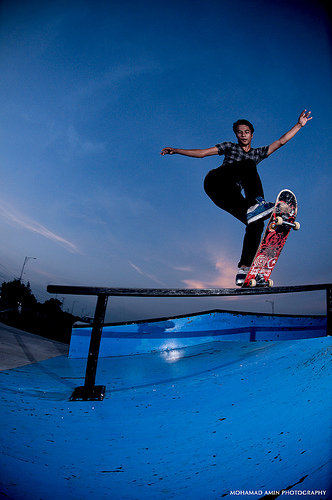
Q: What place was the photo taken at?
A: It was taken at the skate park.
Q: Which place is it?
A: It is a skate park.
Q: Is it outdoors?
A: Yes, it is outdoors.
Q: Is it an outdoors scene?
A: Yes, it is outdoors.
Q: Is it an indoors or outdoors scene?
A: It is outdoors.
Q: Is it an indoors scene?
A: No, it is outdoors.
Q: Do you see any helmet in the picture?
A: No, there are no helmets.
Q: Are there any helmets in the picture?
A: No, there are no helmets.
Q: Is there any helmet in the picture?
A: No, there are no helmets.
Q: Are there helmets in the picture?
A: No, there are no helmets.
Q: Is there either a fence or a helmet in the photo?
A: No, there are no helmets or fences.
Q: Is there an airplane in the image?
A: No, there are no airplanes.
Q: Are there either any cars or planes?
A: No, there are no planes or cars.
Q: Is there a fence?
A: No, there are no fences.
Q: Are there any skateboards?
A: Yes, there is a skateboard.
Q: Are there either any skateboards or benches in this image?
A: Yes, there is a skateboard.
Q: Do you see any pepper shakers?
A: No, there are no pepper shakers.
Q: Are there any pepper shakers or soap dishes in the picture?
A: No, there are no pepper shakers or soap dishes.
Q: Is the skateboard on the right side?
A: Yes, the skateboard is on the right of the image.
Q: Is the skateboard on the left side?
A: No, the skateboard is on the right of the image.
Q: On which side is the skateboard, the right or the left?
A: The skateboard is on the right of the image.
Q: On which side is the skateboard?
A: The skateboard is on the right of the image.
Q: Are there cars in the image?
A: No, there are no cars.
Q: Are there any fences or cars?
A: No, there are no cars or fences.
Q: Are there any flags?
A: No, there are no flags.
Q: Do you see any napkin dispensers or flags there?
A: No, there are no flags or napkin dispensers.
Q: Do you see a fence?
A: No, there are no fences.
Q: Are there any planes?
A: No, there are no planes.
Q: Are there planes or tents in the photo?
A: No, there are no planes or tents.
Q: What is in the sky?
A: The clouds are in the sky.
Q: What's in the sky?
A: The clouds are in the sky.